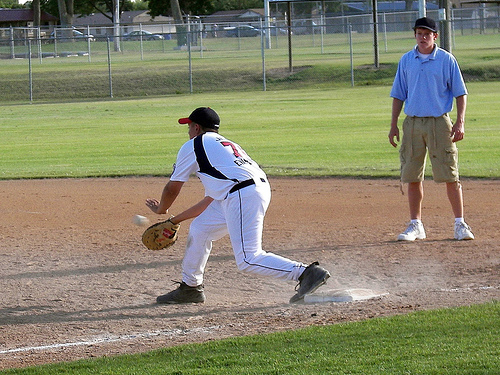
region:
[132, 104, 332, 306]
a baseball player catching a ball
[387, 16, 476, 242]
Coach watching player catch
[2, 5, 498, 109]
Fence surrounding a ballpark.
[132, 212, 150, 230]
a thrown softball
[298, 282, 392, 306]
Dust on a pitcher's mound.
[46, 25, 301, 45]
Spectators vehicles parked outside the fence.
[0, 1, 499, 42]
Homes resting in a row.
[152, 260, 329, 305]
Baseball player's kleats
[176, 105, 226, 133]
Black and red baseball cap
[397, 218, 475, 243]
White athletic shoes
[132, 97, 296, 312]
this is a baseball player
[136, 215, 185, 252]
he is catching a ball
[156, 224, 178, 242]
this is a glove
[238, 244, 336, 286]
the leg is behind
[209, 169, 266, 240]
the jersey is white in color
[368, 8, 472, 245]
the boy is standing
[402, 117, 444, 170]
he is wearing shorts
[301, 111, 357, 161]
the grass is green in color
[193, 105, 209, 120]
he is wearing a cap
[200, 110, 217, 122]
the cap is black in color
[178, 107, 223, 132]
A black and red baseball hat.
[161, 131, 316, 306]
A baseball uniform.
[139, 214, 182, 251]
A brown, red, and black baseball mit.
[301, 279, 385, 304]
A white baseball plate.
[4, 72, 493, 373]
A baseball field.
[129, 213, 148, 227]
A baseball.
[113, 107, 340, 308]
A man trying to catch a baseball.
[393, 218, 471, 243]
A pair of white sneakers.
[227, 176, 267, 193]
A black belt.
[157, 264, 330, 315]
Black cleats.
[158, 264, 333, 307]
A pair of black cleats.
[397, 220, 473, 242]
A pair of white tennis shoes.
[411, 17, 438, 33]
A black hat.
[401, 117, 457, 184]
A pair of beige cargo shorts.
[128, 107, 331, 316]
A guy catching a baseball.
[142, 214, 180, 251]
A brown baseball glove.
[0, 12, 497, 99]
A grey, chain linked fence.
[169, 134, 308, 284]
A black, white and red baseball uniform.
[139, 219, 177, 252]
a light brown baseball glove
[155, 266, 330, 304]
a black pair of baseball cleats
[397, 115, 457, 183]
a pair of tan cargo shorts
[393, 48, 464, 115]
a blue short sleeve collard shirt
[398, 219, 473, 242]
a pair of white tennis shoes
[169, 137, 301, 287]
a white and black baseball uniform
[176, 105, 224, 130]
a black hat with red bill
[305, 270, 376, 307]
a base on a baseball diamond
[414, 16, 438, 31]
a dark color ball cap